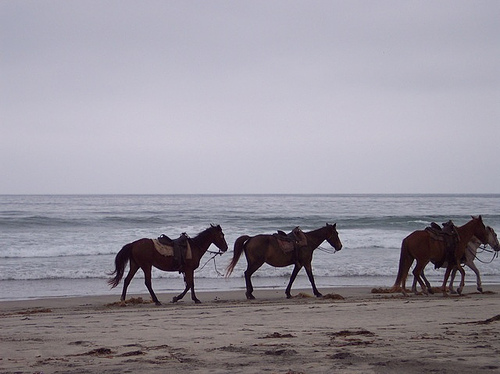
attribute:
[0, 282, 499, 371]
beach — sandy, seaweedy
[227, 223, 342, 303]
horse — pack, running, brown, walking, lined, light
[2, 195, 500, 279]
ocean — crashing, water, large, wavy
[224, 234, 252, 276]
tail — bronw, beautiful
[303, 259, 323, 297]
leg — brown